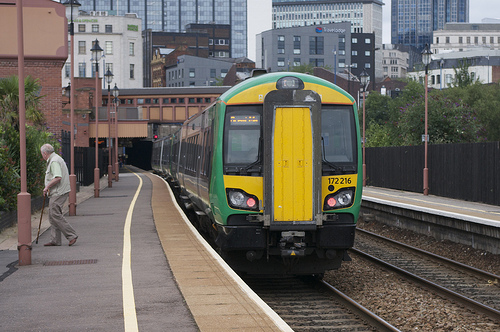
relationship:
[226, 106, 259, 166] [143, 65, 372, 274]
window of train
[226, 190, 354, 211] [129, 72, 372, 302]
headlights of train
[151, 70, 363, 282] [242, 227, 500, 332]
train on track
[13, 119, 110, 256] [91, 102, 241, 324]
man on platform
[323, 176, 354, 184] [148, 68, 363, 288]
numbers on train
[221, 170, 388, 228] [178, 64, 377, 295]
headlights on train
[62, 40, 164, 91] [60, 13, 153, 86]
window on building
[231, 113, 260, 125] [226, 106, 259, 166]
lights inside window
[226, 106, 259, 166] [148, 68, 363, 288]
window on train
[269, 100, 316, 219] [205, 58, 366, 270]
panel on train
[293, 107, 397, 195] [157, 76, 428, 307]
window on train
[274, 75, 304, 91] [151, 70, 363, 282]
sign on train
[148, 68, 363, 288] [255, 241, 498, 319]
train on track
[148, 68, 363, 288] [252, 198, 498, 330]
train on track